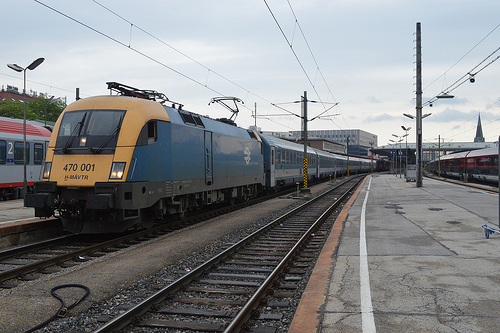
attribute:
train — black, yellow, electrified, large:
[17, 83, 390, 239]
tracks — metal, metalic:
[0, 229, 327, 331]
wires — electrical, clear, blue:
[32, 1, 500, 86]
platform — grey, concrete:
[305, 170, 499, 326]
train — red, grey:
[1, 109, 49, 202]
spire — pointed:
[469, 105, 488, 136]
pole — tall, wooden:
[407, 20, 436, 189]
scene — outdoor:
[5, 4, 499, 331]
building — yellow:
[267, 124, 384, 146]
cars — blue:
[265, 129, 389, 186]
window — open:
[143, 115, 161, 150]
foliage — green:
[3, 85, 66, 118]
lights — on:
[40, 132, 128, 183]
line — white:
[345, 175, 384, 331]